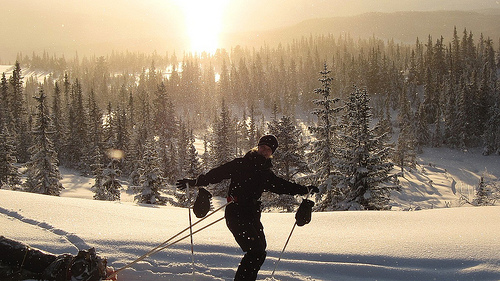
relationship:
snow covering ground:
[397, 203, 483, 256] [1, 188, 485, 275]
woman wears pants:
[208, 105, 328, 272] [223, 216, 282, 278]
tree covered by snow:
[82, 85, 112, 178] [329, 110, 386, 176]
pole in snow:
[104, 196, 245, 278] [94, 235, 239, 279]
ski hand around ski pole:
[304, 174, 349, 196] [256, 187, 321, 279]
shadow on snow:
[97, 236, 499, 280] [8, 195, 495, 274]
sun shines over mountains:
[174, 4, 226, 44] [266, 7, 499, 46]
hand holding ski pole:
[172, 174, 194, 192] [181, 182, 201, 278]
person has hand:
[167, 105, 371, 252] [172, 174, 194, 192]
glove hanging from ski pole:
[292, 196, 330, 229] [271, 187, 317, 277]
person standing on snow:
[172, 135, 322, 281] [0, 45, 499, 281]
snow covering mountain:
[0, 45, 499, 281] [3, 0, 497, 278]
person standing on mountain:
[172, 135, 322, 281] [3, 0, 497, 278]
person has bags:
[172, 135, 322, 281] [184, 137, 236, 217]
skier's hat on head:
[245, 127, 280, 153] [257, 131, 278, 160]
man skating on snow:
[180, 129, 322, 279] [0, 65, 499, 278]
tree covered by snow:
[293, 59, 349, 209] [1, 94, 497, 279]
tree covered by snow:
[23, 81, 65, 193] [0, 24, 499, 279]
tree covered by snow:
[293, 59, 349, 209] [0, 24, 499, 279]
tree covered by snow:
[128, 139, 169, 203] [0, 24, 499, 279]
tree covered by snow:
[88, 150, 110, 200] [0, 24, 499, 279]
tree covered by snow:
[327, 89, 400, 212] [0, 24, 499, 279]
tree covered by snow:
[128, 139, 169, 203] [142, 184, 151, 196]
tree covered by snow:
[327, 89, 400, 208] [0, 24, 499, 279]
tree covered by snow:
[474, 175, 488, 204] [0, 24, 499, 279]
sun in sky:
[174, 4, 226, 44] [0, 3, 496, 66]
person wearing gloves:
[172, 135, 322, 281] [173, 174, 201, 192]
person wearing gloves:
[172, 135, 322, 281] [304, 181, 321, 198]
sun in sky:
[174, 4, 226, 44] [2, 1, 483, 53]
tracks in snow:
[124, 233, 234, 278] [2, 185, 485, 279]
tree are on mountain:
[128, 139, 169, 203] [234, 9, 498, 53]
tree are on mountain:
[82, 85, 112, 178] [234, 9, 498, 53]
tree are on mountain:
[327, 89, 400, 212] [234, 9, 498, 53]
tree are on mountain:
[23, 81, 65, 193] [234, 9, 498, 53]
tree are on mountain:
[88, 150, 110, 200] [234, 9, 498, 53]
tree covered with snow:
[327, 89, 400, 212] [296, 86, 498, 278]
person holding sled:
[172, 135, 322, 281] [9, 231, 111, 279]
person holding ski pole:
[172, 135, 322, 281] [264, 187, 317, 280]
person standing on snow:
[172, 135, 322, 281] [370, 212, 469, 262]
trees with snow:
[0, 68, 389, 199] [0, 45, 499, 281]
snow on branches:
[0, 45, 499, 281] [370, 144, 401, 193]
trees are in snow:
[1, 62, 498, 192] [332, 209, 489, 257]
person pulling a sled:
[172, 135, 322, 281] [25, 238, 113, 276]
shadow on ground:
[97, 236, 496, 279] [2, 64, 497, 278]